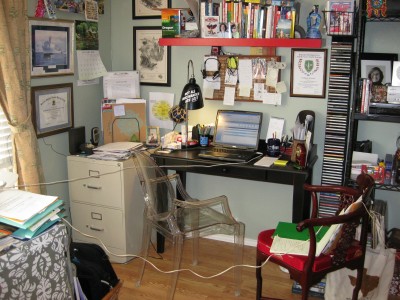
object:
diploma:
[31, 83, 73, 138]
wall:
[19, 0, 110, 259]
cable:
[0, 151, 262, 187]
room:
[0, 0, 400, 300]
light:
[179, 58, 205, 150]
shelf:
[159, 37, 322, 48]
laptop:
[199, 109, 264, 161]